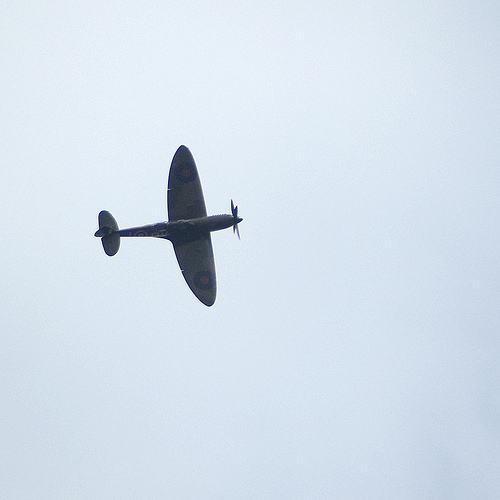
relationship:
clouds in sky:
[26, 31, 111, 95] [4, 2, 499, 499]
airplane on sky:
[93, 143, 241, 306] [4, 2, 499, 499]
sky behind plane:
[292, 147, 403, 227] [108, 125, 250, 302]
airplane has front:
[93, 143, 241, 306] [215, 186, 247, 242]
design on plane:
[190, 267, 215, 299] [59, 138, 264, 317]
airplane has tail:
[91, 137, 246, 312] [91, 206, 123, 261]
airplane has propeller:
[93, 143, 241, 306] [218, 193, 262, 250]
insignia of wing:
[189, 265, 218, 297] [177, 237, 217, 307]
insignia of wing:
[193, 268, 214, 290] [166, 146, 209, 213]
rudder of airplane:
[88, 224, 101, 245] [88, 139, 259, 315]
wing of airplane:
[174, 233, 217, 306] [79, 96, 306, 336]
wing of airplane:
[164, 143, 205, 223] [79, 96, 306, 336]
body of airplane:
[94, 197, 242, 255] [121, 133, 228, 292]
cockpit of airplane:
[155, 220, 191, 239] [94, 143, 242, 306]